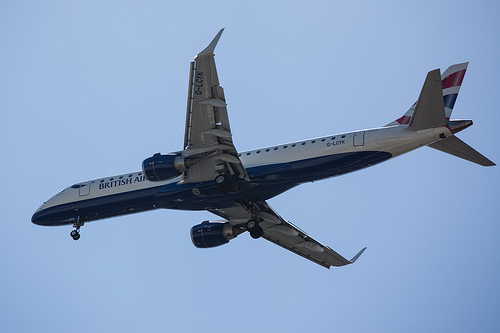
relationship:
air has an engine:
[0, 1, 497, 333] [140, 153, 187, 182]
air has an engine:
[0, 1, 497, 333] [191, 220, 254, 248]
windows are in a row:
[89, 133, 348, 186] [82, 133, 347, 188]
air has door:
[0, 1, 497, 333] [353, 130, 366, 147]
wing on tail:
[413, 67, 446, 127] [376, 61, 499, 170]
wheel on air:
[246, 220, 263, 239] [0, 1, 497, 333]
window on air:
[255, 149, 261, 154] [0, 1, 497, 333]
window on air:
[291, 143, 295, 148] [0, 1, 497, 333]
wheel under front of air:
[67, 230, 79, 241] [0, 1, 497, 333]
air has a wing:
[0, 1, 497, 333] [180, 27, 248, 188]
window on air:
[329, 136, 336, 141] [0, 1, 497, 333]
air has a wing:
[0, 1, 497, 333] [210, 203, 369, 270]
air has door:
[0, 1, 497, 333] [78, 181, 90, 197]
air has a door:
[0, 1, 497, 333] [78, 181, 90, 197]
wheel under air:
[213, 174, 227, 190] [0, 1, 497, 333]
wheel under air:
[246, 220, 263, 239] [0, 1, 497, 333]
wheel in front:
[67, 230, 79, 241] [29, 173, 133, 239]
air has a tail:
[0, 1, 497, 333] [376, 61, 499, 170]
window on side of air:
[119, 175, 124, 180] [0, 1, 497, 333]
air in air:
[0, 1, 497, 333] [0, 1, 497, 333]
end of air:
[376, 61, 499, 170] [0, 1, 497, 333]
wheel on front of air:
[67, 230, 79, 241] [0, 1, 497, 333]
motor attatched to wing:
[191, 220, 254, 248] [210, 203, 369, 270]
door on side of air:
[353, 130, 366, 147] [0, 1, 497, 333]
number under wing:
[193, 68, 205, 100] [180, 27, 248, 188]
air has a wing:
[0, 1, 497, 333] [413, 67, 446, 127]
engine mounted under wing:
[191, 220, 254, 248] [210, 203, 369, 270]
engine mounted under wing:
[140, 153, 187, 182] [180, 27, 248, 188]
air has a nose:
[0, 1, 497, 333] [23, 182, 76, 229]